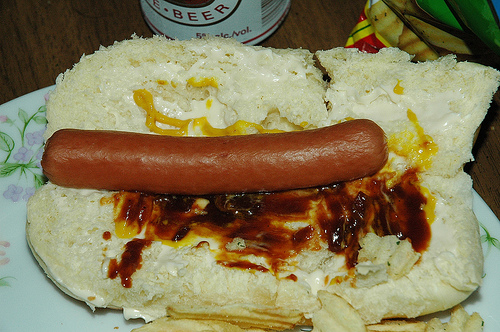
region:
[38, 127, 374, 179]
One hot dog is seen.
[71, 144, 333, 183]
Hot dog is brown color.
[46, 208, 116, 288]
Bread is white color.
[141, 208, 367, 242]
Sauce is red color.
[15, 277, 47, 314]
Plate is white color.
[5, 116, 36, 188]
Floral prints in plate.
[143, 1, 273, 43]
One beer can in table.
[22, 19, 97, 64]
Table is brown color.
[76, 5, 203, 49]
can is in table.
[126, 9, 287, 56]
Can is white color.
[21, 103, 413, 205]
hot dog is pink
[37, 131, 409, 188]
A brown hot dog.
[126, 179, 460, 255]
Brown sauce on bun.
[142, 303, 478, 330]
Plain white potato chips.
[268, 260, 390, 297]
Mayonaisse on a bun.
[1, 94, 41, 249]
Purple and green flowers on plate.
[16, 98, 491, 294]
Plate with a hot dog on it.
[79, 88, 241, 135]
Mustard on a bun.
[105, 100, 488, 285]
Hot dog and sauce on bun.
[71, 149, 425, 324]
Hot dog and chips on a plate.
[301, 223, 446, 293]
Potato chip on bun.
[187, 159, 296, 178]
part of a sausaage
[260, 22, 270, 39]
bottom part of a beer can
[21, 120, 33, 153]
flowers on a plate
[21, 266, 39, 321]
section of a plate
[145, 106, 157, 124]
section of a mustard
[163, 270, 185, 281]
inside part of a bread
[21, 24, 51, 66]
section of a table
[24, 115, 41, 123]
green flower drawing on a plate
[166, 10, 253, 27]
section of a beer can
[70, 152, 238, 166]
section of a brown smokie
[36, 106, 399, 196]
a lightly cooked wiener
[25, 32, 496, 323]
a wiener too short for the bun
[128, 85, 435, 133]
a smudge of mustard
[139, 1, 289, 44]
a can of beer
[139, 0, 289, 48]
a white can of beer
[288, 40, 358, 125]
a tear in hot dog bun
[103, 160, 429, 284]
a sauce of some kind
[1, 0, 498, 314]
hot dog on a table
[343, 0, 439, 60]
a plastic bag by the hot dog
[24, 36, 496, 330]
a high carb bun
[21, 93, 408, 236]
hot dog in a bun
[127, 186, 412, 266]
sauce on the bun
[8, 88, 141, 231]
top of the hot dog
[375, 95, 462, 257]
yellow and brown sauce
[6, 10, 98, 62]
lines on the table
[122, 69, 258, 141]
white and yellow sauce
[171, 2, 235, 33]
word on the bottle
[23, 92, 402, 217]
brown hot dog in the sauced bun